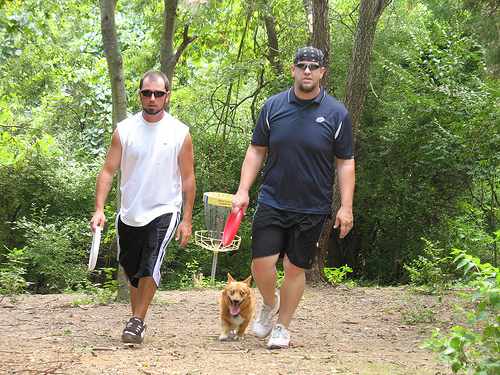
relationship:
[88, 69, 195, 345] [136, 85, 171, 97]
guy wearing sunglasses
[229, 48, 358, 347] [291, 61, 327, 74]
guy wearing sunglasses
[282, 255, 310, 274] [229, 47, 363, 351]
knee of guy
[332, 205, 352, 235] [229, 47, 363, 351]
hand of guy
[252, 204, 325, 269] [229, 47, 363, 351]
shorts of guy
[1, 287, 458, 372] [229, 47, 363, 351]
gravel by guy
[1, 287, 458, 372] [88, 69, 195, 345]
gravel by guy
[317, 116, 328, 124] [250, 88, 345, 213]
logo on shirt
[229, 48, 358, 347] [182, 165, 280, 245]
guy carrying frisbee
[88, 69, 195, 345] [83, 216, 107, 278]
guy carrying frisbee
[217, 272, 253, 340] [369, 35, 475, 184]
corgi in woods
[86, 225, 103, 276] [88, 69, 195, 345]
frisbee in guy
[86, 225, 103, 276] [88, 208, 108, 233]
frisbee in hand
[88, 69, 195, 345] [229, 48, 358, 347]
guy walking in guy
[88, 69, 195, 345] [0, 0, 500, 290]
guy walking in woods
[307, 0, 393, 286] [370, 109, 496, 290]
tree in woods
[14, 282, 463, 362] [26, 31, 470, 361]
path in woods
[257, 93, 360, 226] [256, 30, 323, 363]
shirt on man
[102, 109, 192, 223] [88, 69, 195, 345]
shirt on guy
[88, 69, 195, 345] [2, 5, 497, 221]
guy in woods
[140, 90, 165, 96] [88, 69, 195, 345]
sunglasses on guy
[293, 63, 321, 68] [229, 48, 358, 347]
sunglasses on guy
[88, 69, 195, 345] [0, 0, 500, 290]
guy in woods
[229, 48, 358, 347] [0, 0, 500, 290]
guy in woods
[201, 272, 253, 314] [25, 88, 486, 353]
corgi walking in woods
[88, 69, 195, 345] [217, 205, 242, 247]
guy carrying a frisbee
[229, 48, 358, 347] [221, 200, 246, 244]
guy playing disc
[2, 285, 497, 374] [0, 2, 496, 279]
trail leading through forest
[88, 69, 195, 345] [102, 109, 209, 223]
guy wearing shirt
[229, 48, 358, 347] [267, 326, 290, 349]
guy wearing shoe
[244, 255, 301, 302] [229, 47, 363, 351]
knee of guy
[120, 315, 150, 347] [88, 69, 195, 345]
shoe on guy